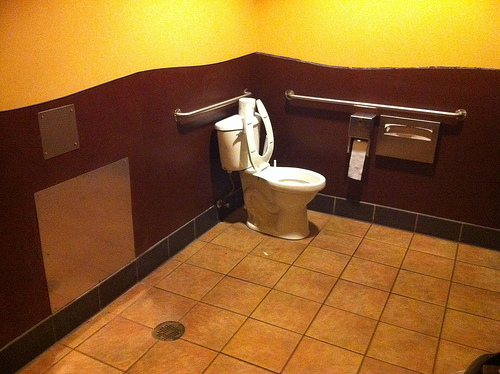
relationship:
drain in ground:
[133, 309, 194, 362] [106, 258, 295, 373]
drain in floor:
[133, 309, 194, 362] [155, 254, 330, 351]